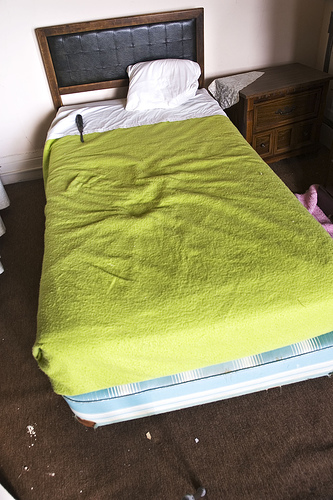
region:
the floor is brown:
[240, 440, 259, 490]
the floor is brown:
[229, 472, 251, 497]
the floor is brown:
[218, 486, 230, 495]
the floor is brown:
[214, 469, 228, 489]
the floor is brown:
[240, 487, 249, 497]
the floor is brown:
[222, 464, 241, 498]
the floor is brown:
[224, 481, 243, 496]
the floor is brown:
[216, 448, 259, 497]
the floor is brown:
[237, 451, 251, 494]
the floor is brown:
[226, 440, 279, 498]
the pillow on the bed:
[125, 59, 199, 107]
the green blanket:
[34, 125, 331, 384]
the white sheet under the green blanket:
[44, 101, 227, 134]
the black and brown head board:
[34, 6, 205, 97]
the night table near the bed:
[217, 58, 327, 161]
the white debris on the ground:
[20, 425, 214, 498]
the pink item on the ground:
[298, 181, 332, 237]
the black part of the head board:
[61, 35, 118, 73]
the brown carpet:
[226, 405, 291, 458]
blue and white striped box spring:
[57, 333, 331, 429]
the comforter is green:
[103, 186, 280, 306]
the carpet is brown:
[144, 435, 306, 486]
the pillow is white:
[112, 56, 207, 104]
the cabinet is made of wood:
[238, 77, 316, 148]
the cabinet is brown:
[236, 78, 329, 142]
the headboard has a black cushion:
[40, 27, 201, 89]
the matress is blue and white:
[97, 372, 265, 398]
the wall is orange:
[224, 20, 283, 66]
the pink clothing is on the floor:
[298, 178, 332, 218]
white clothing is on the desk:
[209, 75, 259, 105]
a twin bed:
[40, 83, 329, 425]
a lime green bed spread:
[35, 107, 328, 390]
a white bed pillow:
[123, 59, 196, 109]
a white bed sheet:
[43, 78, 229, 146]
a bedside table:
[217, 57, 325, 165]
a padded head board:
[28, 9, 206, 103]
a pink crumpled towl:
[288, 180, 330, 234]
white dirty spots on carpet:
[10, 419, 214, 492]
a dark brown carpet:
[1, 182, 323, 493]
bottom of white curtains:
[0, 160, 15, 281]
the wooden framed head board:
[34, 8, 206, 96]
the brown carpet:
[223, 414, 313, 488]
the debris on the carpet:
[15, 423, 212, 499]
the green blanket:
[62, 150, 267, 282]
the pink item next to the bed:
[298, 186, 332, 238]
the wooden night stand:
[234, 58, 324, 160]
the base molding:
[0, 149, 43, 188]